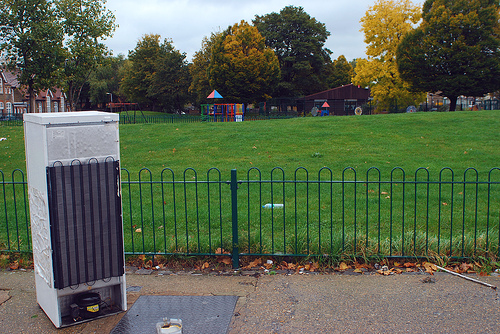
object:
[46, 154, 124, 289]
coils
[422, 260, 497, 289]
stick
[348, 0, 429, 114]
leaves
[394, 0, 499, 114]
leaves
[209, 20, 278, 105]
leaves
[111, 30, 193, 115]
leaves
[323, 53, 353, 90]
leaves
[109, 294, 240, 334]
metal plate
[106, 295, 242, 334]
gray plate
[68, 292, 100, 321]
motor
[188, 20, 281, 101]
fall season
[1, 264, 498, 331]
street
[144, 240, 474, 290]
leaves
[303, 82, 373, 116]
house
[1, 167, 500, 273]
fencing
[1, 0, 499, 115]
trees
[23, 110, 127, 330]
fridge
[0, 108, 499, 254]
grass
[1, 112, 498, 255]
field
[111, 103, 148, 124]
swing set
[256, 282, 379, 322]
wet cement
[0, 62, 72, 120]
building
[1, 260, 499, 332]
sidewalk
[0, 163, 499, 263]
fence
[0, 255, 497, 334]
ground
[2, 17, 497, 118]
background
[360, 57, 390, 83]
leaves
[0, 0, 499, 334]
park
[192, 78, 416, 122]
playground